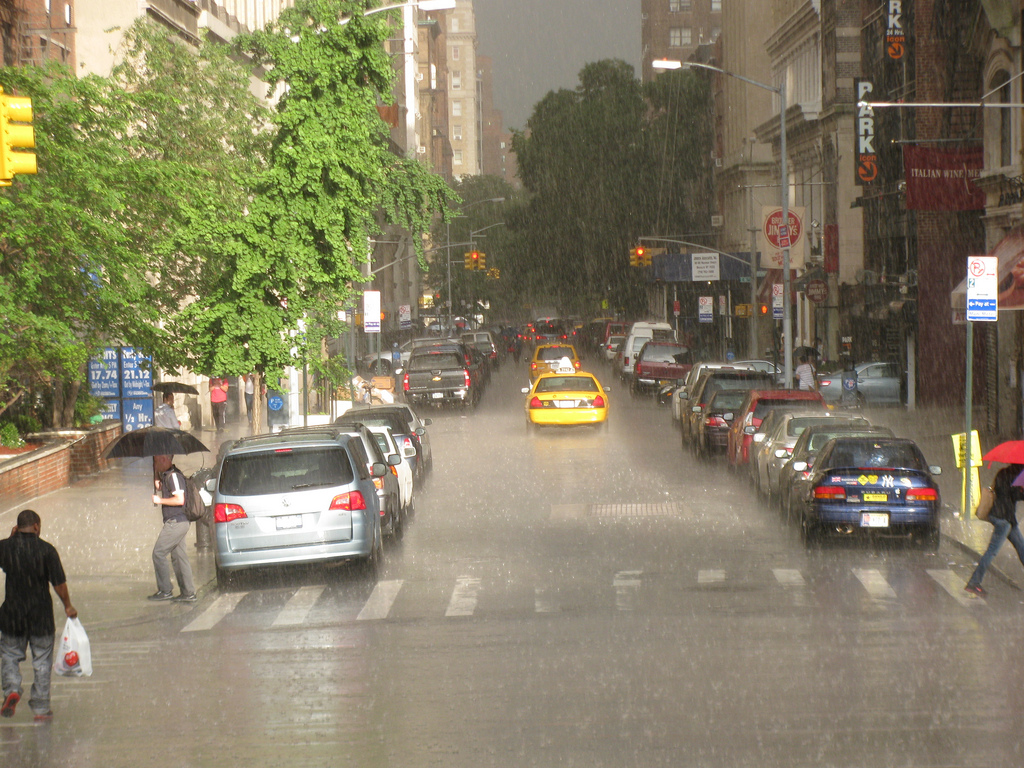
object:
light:
[2, 74, 52, 191]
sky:
[480, 1, 632, 66]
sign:
[846, 46, 910, 288]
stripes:
[160, 526, 1006, 641]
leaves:
[104, 4, 455, 379]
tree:
[2, 1, 104, 450]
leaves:
[176, 173, 378, 275]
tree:
[103, 0, 466, 425]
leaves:
[135, 44, 214, 152]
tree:
[138, 0, 408, 384]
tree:
[0, 0, 133, 430]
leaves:
[317, 24, 397, 124]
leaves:
[570, 67, 642, 178]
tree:
[507, 54, 649, 294]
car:
[361, 415, 454, 513]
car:
[677, 325, 786, 468]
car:
[526, 336, 594, 376]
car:
[180, 404, 397, 586]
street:
[23, 338, 1014, 767]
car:
[798, 428, 940, 554]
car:
[504, 353, 616, 432]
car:
[515, 331, 583, 375]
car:
[384, 336, 494, 414]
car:
[616, 325, 685, 392]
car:
[625, 341, 693, 400]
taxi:
[515, 331, 598, 375]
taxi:
[515, 307, 610, 374]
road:
[474, 415, 739, 720]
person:
[135, 435, 223, 626]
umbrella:
[88, 424, 220, 460]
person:
[5, 497, 96, 744]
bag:
[46, 603, 107, 683]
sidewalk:
[0, 372, 428, 764]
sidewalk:
[617, 307, 1022, 579]